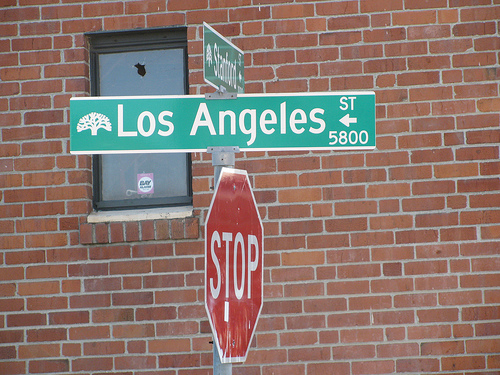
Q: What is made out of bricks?
A: The building.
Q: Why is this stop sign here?
A: To stop traffic.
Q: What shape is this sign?
A: Octagon.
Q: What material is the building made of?
A: Brick.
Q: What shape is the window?
A: Rectangle.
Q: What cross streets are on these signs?
A: Stanford and Los Angeles.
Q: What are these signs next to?
A: A brick building.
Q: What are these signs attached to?
A: A metal pole.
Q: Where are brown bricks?
A: On a building.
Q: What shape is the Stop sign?
A: Octagonal.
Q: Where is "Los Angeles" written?
A: On street sign.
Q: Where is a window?
A: On the building.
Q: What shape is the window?
A: Rectangular.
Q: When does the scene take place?
A: During daytime.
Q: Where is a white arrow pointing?
A: To the left.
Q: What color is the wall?
A: Brick.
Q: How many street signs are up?
A: Two.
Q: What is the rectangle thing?
A: Window.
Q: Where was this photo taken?
A: Los angeles st.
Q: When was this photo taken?
A: During the day.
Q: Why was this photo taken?
A: To show the streets.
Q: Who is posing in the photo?
A: No one.